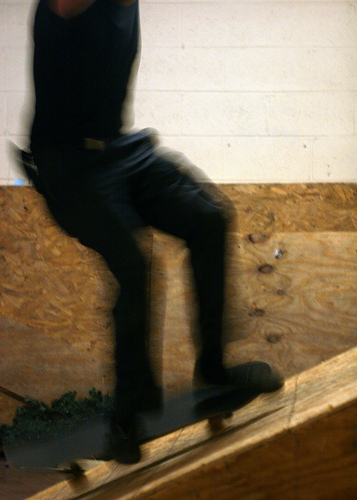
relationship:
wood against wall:
[241, 186, 343, 353] [221, 17, 349, 140]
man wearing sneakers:
[22, 2, 284, 465] [109, 143, 305, 391]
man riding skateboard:
[22, 2, 284, 465] [6, 359, 273, 478]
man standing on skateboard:
[22, 2, 282, 438] [5, 379, 258, 493]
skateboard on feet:
[12, 373, 287, 480] [98, 355, 272, 418]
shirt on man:
[28, 0, 145, 150] [22, 2, 282, 438]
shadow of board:
[67, 405, 287, 498] [68, 385, 259, 472]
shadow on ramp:
[67, 405, 287, 498] [38, 347, 355, 498]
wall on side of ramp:
[0, 183, 354, 428] [38, 347, 355, 498]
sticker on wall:
[9, 175, 32, 190] [2, 88, 49, 191]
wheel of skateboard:
[66, 471, 88, 490] [3, 360, 272, 468]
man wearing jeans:
[22, 2, 284, 465] [51, 166, 252, 382]